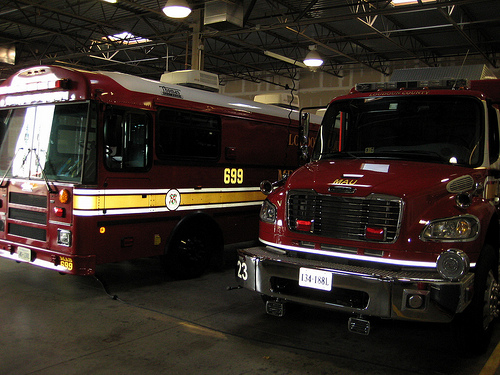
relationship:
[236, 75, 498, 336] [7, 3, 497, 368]
fire truck in garage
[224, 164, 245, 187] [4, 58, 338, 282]
gold number written on side of bus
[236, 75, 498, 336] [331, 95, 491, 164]
fire truck has a windshield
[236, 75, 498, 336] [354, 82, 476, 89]
fire truck has lights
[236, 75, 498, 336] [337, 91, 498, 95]
fire truck has roof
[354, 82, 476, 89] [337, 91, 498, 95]
lights are on top of roof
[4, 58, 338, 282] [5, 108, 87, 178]
bus has windshield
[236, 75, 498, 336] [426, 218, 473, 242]
fire truck has headlight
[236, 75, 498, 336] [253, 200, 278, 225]
fire truck has headlight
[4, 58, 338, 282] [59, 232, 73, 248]
bus had headlight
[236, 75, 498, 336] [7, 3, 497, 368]
fire truck inside garage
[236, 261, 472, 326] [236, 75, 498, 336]
bumper at front of fire truck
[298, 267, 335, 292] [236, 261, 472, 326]
license plate in front of bumper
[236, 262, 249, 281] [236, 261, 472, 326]
number 23 printed on left bumper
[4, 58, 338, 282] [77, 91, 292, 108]
bus has roof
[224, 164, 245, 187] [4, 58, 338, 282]
gold number on side of bus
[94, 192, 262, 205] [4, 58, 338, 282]
lines are on side of bus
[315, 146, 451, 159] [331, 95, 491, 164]
wipers over a windshield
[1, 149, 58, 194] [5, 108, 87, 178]
wipers over a windshield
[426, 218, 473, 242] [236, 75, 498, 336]
headlight in front of fire truck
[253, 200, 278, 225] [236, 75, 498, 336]
headlight in front of fire truck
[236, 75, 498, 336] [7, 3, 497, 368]
fire truck parked in garage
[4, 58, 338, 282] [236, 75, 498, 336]
bus to left of fire truck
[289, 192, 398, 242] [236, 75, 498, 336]
grill in front of fire truck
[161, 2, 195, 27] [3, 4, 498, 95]
light hanging from ceiling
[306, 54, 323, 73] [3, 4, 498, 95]
light hanging from ceiling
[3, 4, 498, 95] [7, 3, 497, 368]
ceiling inside garage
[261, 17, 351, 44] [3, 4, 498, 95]
steel girders support ceiling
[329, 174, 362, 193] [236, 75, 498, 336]
tag on front of fire truck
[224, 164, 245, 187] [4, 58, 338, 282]
gold number painted side of bus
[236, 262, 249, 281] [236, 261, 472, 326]
number 23 on front of bumper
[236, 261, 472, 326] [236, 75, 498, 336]
bumper in front of fire truck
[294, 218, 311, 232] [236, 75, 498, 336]
emergency light in front of fire truck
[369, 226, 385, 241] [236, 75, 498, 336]
emergency lights in front of fire truck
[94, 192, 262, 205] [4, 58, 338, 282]
lines run along side of bus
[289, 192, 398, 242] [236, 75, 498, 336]
grill in front of truck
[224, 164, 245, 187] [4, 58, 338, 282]
gold number on side of a bus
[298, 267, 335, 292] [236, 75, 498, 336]
license plate in front of fire truck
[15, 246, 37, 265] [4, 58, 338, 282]
license plate in front of bus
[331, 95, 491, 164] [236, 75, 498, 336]
windshield in front of fire truck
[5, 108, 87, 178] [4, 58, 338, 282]
windshield in front of bus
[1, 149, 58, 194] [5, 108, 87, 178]
wipers are in front of windshield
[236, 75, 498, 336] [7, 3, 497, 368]
fire truck inside a garage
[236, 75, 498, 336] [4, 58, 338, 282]
fire truck to right of a bus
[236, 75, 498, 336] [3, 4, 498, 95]
fire truck below ceiling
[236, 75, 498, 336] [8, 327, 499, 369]
fire truck parked on floor